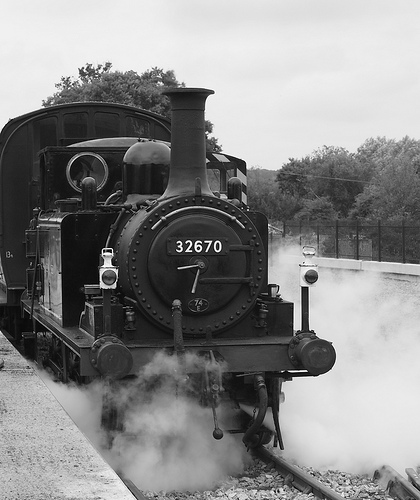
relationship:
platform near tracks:
[1, 86, 343, 362] [112, 402, 401, 496]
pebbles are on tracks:
[225, 490, 237, 499] [71, 386, 419, 498]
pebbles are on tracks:
[138, 446, 384, 500] [71, 386, 419, 498]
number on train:
[177, 237, 223, 251] [1, 74, 341, 452]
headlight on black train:
[95, 264, 122, 292] [0, 87, 336, 451]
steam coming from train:
[27, 346, 259, 490] [1, 74, 341, 452]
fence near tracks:
[271, 219, 418, 261] [75, 394, 337, 495]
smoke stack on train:
[164, 80, 216, 190] [1, 74, 341, 452]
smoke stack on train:
[30, 245, 419, 496] [1, 74, 341, 452]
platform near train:
[0, 332, 137, 500] [1, 74, 341, 452]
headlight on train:
[102, 269, 116, 285] [1, 74, 341, 452]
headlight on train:
[303, 270, 318, 282] [1, 74, 341, 452]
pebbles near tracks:
[138, 446, 384, 500] [0, 326, 420, 498]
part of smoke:
[138, 405, 200, 462] [56, 239, 418, 499]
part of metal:
[142, 243, 177, 291] [135, 227, 182, 291]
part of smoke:
[138, 405, 200, 462] [99, 349, 254, 494]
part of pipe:
[257, 393, 265, 409] [240, 377, 272, 450]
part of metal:
[155, 250, 177, 291] [26, 185, 248, 362]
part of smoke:
[152, 427, 187, 456] [133, 361, 240, 482]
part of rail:
[21, 430, 47, 465] [16, 365, 97, 494]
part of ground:
[229, 471, 258, 489] [139, 456, 311, 498]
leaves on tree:
[40, 61, 220, 153] [41, 60, 222, 151]